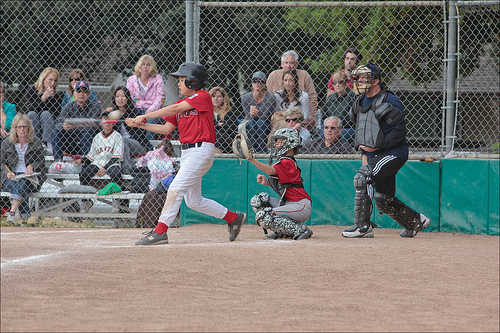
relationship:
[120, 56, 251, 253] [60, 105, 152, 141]
boy holding bat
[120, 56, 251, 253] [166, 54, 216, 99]
boy wearing helmet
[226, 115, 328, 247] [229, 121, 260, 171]
boy wearing glove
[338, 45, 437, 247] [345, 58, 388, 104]
man wearing faceguard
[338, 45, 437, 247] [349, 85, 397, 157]
umpire wearing vest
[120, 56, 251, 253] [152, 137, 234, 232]
boy wearing pants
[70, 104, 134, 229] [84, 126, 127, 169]
boy wearing jersey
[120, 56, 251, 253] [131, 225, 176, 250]
boy wearing shoe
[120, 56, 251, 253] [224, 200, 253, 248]
boy wearing shoe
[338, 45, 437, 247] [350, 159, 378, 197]
umpire wearing kneepad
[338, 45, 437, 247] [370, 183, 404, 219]
umpire wearing kneepad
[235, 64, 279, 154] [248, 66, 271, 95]
woman wearing cap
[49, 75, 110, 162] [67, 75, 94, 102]
man wearing cap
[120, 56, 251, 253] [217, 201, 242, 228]
boy wearing sock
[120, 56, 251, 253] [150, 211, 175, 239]
boy wearing sock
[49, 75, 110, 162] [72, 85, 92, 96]
man wearing sunglasses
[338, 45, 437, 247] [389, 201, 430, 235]
man wearing shinguards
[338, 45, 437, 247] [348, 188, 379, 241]
man wearing shinguards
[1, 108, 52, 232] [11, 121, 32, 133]
woman wearing glasses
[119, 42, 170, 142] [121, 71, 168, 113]
woman wearing jacket